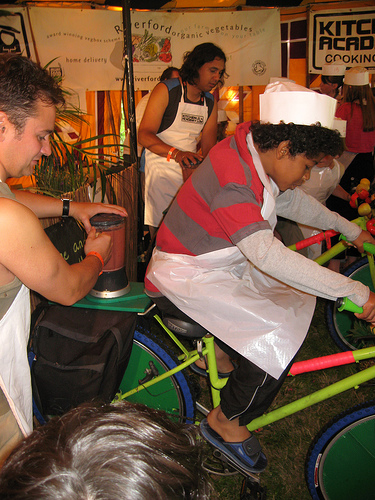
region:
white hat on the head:
[253, 74, 340, 134]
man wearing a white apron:
[137, 37, 231, 243]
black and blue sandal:
[192, 410, 277, 475]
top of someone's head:
[0, 401, 221, 499]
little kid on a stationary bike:
[44, 80, 374, 498]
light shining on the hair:
[69, 408, 170, 499]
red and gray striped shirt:
[144, 122, 274, 287]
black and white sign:
[307, 9, 373, 70]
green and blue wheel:
[118, 331, 200, 454]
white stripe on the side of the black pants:
[224, 365, 266, 426]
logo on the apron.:
[181, 112, 203, 123]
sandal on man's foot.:
[236, 443, 261, 467]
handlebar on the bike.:
[337, 298, 361, 318]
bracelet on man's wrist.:
[87, 253, 105, 272]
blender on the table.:
[109, 226, 123, 270]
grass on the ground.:
[288, 422, 311, 444]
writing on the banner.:
[158, 21, 201, 39]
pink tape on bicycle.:
[315, 351, 350, 376]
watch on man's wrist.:
[59, 197, 68, 220]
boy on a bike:
[40, 66, 374, 494]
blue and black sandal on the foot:
[199, 414, 272, 474]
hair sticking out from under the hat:
[245, 112, 345, 167]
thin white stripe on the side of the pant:
[223, 371, 269, 432]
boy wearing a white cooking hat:
[258, 75, 333, 123]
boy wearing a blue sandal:
[199, 411, 269, 472]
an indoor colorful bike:
[27, 223, 373, 498]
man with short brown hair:
[3, 50, 67, 181]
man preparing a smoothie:
[79, 201, 129, 296]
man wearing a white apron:
[147, 77, 209, 230]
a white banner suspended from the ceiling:
[29, 5, 281, 86]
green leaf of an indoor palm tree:
[24, 54, 136, 204]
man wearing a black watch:
[60, 197, 71, 218]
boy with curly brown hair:
[252, 121, 343, 191]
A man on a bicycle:
[143, 73, 372, 473]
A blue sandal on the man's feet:
[197, 406, 271, 471]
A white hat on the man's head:
[259, 73, 338, 130]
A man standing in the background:
[136, 40, 228, 238]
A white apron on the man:
[141, 78, 209, 226]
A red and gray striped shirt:
[145, 122, 271, 299]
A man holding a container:
[0, 53, 132, 463]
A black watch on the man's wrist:
[57, 193, 73, 217]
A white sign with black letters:
[304, 6, 373, 78]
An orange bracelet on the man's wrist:
[165, 143, 177, 160]